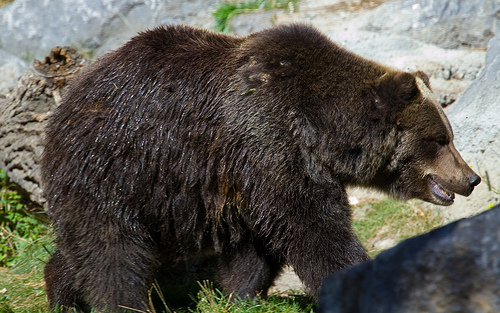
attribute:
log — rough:
[3, 39, 87, 215]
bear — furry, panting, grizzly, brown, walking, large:
[36, 20, 493, 312]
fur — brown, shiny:
[99, 63, 314, 235]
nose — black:
[463, 165, 481, 188]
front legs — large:
[218, 232, 385, 297]